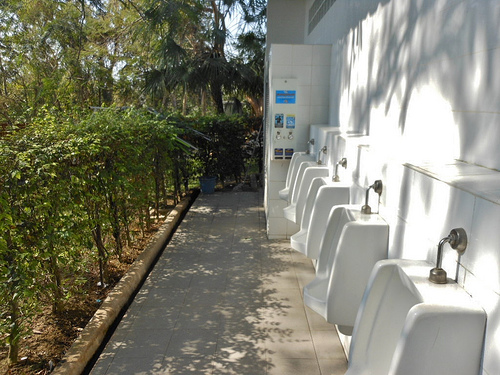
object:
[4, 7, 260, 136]
trees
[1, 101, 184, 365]
trees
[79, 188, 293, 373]
shadow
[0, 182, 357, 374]
ground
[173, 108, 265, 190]
trees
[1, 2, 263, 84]
sky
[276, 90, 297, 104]
sign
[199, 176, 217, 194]
pot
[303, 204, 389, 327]
urinal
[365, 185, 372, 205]
pipe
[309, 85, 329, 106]
tile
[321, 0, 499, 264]
shadow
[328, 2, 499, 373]
wall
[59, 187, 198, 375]
curb